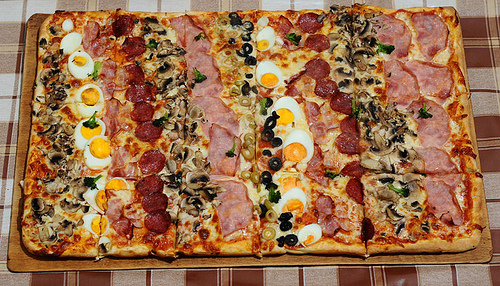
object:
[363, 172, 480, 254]
crust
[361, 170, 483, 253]
slice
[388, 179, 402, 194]
broccoli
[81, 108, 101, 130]
broccoli piece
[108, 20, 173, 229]
meats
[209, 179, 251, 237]
ham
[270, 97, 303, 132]
egg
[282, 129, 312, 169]
egg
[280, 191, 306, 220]
egg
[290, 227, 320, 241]
egg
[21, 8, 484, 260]
pizza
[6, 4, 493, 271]
board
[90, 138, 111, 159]
yolk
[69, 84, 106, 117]
egg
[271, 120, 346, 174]
spice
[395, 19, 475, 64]
spice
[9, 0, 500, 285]
tablecloth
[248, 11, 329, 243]
egg slices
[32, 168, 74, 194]
mushrooms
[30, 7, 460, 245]
toppings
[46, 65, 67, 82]
mushroom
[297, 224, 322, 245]
eggs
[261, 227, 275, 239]
olive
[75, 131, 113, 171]
egg